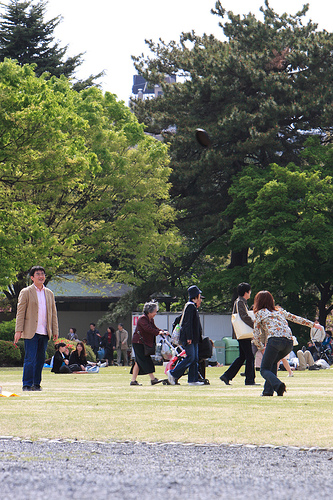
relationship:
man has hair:
[14, 262, 65, 398] [23, 264, 48, 278]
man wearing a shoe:
[170, 282, 215, 385] [164, 364, 184, 387]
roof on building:
[41, 269, 131, 297] [22, 263, 162, 361]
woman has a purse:
[170, 295, 221, 385] [195, 333, 220, 366]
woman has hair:
[126, 296, 172, 388] [139, 298, 160, 318]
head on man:
[26, 264, 53, 285] [14, 262, 65, 398]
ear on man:
[29, 268, 38, 286] [14, 262, 65, 398]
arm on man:
[8, 289, 26, 346] [14, 262, 65, 398]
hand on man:
[8, 327, 26, 350] [14, 262, 65, 398]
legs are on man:
[19, 338, 51, 393] [14, 262, 65, 398]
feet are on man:
[20, 379, 54, 396] [14, 262, 65, 398]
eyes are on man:
[25, 268, 54, 282] [14, 262, 65, 398]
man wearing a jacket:
[14, 262, 65, 398] [8, 282, 61, 343]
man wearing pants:
[14, 262, 65, 398] [21, 336, 53, 392]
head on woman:
[134, 298, 163, 325] [126, 296, 172, 388]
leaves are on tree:
[4, 106, 138, 229] [2, 58, 192, 318]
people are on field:
[17, 267, 333, 389] [0, 363, 333, 448]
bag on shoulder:
[170, 302, 194, 345] [180, 298, 203, 315]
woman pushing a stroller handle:
[126, 296, 172, 388] [160, 324, 194, 361]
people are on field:
[44, 330, 100, 375] [0, 363, 333, 448]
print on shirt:
[259, 312, 293, 342] [246, 303, 319, 363]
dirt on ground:
[17, 452, 131, 499] [2, 438, 332, 499]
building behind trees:
[22, 263, 162, 361] [4, 3, 329, 314]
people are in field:
[44, 330, 100, 375] [0, 363, 333, 448]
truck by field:
[126, 306, 250, 361] [0, 363, 333, 448]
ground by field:
[2, 438, 332, 499] [0, 363, 333, 448]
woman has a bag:
[170, 295, 221, 385] [164, 317, 192, 349]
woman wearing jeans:
[247, 293, 326, 395] [255, 333, 293, 393]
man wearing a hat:
[170, 282, 215, 385] [182, 276, 207, 308]